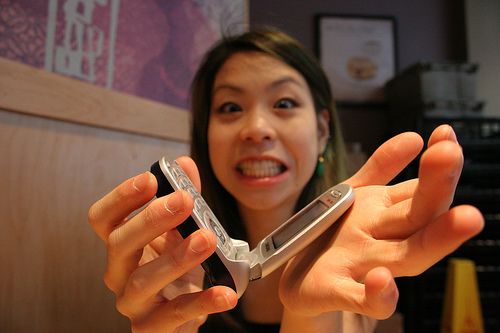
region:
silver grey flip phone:
[143, 156, 352, 295]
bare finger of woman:
[348, 265, 418, 317]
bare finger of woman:
[360, 202, 489, 272]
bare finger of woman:
[378, 140, 470, 234]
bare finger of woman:
[430, 124, 457, 144]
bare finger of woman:
[154, 284, 238, 331]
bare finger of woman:
[123, 222, 219, 309]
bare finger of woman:
[87, 168, 160, 233]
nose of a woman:
[237, 112, 277, 144]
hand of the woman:
[381, 99, 457, 311]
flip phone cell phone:
[130, 151, 347, 267]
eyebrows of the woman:
[189, 59, 305, 88]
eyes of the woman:
[205, 98, 305, 116]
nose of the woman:
[235, 117, 272, 157]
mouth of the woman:
[225, 158, 287, 178]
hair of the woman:
[245, 29, 311, 64]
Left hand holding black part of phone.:
[91, 155, 237, 331]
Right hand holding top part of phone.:
[278, 123, 483, 331]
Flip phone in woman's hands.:
[151, 153, 356, 300]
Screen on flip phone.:
[271, 199, 329, 247]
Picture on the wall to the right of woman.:
[312, 12, 400, 109]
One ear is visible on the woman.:
[317, 107, 329, 154]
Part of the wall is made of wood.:
[0, 54, 192, 331]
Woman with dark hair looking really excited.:
[90, 26, 483, 331]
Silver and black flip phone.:
[150, 153, 352, 301]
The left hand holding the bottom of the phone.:
[91, 154, 238, 331]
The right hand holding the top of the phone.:
[279, 123, 482, 332]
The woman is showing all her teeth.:
[236, 158, 283, 176]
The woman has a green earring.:
[318, 152, 325, 176]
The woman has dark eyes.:
[213, 97, 299, 111]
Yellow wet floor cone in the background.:
[441, 258, 485, 332]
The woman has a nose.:
[239, 105, 276, 142]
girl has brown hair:
[197, 25, 364, 171]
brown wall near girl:
[32, 132, 114, 244]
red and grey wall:
[40, 0, 190, 92]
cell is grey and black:
[156, 155, 336, 292]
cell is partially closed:
[170, 146, 340, 278]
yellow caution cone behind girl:
[412, 250, 477, 332]